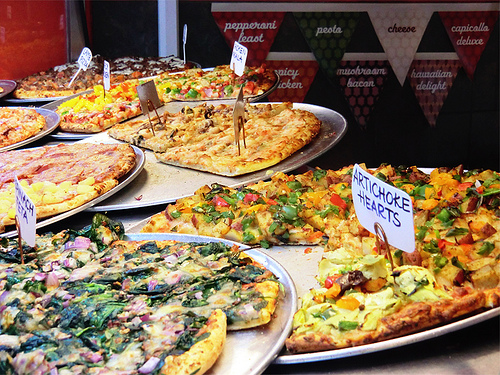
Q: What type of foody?
A: Pizza.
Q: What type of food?
A: Pizza.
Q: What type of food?
A: Pizza.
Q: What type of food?
A: Pizza.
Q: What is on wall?
A: Flags.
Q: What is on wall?
A: Flags.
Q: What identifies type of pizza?
A: Sign.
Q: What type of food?
A: Pizza.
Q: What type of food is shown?
A: Pizza.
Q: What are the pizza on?
A: Pans.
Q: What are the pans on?
A: Table.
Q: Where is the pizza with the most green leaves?
A: Closest pizza on the left.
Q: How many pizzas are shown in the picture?
A: Seven.